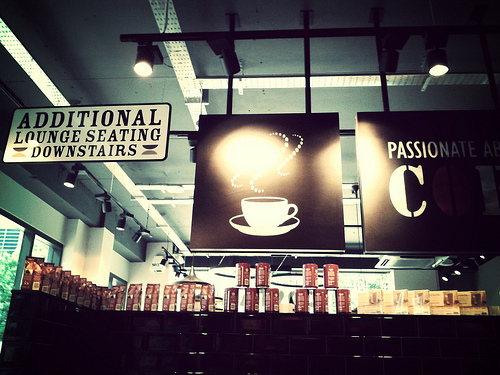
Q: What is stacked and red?
A: Cans.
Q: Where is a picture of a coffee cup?
A: On a sign.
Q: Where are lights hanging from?
A: The ceiling.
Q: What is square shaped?
A: Two signs.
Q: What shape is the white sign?
A: Rectangle.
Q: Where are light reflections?
A: On the black signs.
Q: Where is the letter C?
A: On black sign on the right.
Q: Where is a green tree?
A: Outside the window.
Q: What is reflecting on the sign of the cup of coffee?
A: Light.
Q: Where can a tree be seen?
A: Bottom left corner.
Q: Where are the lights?
A: Hanging from the ceiling.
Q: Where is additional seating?
A: Downstairs.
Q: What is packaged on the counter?
A: Coffee.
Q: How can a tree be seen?
A: Through the window.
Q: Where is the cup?
A: Middle sign.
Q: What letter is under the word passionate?
A: C.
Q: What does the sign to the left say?
A: ADDITIONAL LOUNGE SEATING DOWNSTAIRS.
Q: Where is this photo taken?
A: Coffee shop.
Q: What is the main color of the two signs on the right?
A: Black.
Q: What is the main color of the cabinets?
A: Black.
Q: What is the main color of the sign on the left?
A: White.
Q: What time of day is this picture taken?
A: Taken during the day.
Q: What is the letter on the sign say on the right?
A: C.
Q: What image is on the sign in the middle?
A: Coffee.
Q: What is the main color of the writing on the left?
A: Black.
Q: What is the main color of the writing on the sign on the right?
A: White.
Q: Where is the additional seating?
A: Downstairs.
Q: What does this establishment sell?
A: Coffee.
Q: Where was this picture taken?
A: A restaurant.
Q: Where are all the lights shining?
A: Down.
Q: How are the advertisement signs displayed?
A: Hanging from the ceiling.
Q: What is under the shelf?
A: Tile.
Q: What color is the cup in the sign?
A: White.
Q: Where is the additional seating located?
A: Downstairs.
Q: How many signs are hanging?
A: 3.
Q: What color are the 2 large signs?
A: Brown.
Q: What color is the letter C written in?
A: It is in white.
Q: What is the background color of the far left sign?
A: Off white.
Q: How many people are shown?
A: None.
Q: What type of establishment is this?
A: A restaurant.